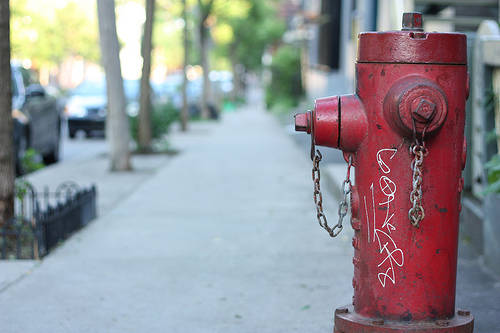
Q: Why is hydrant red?
A: Security.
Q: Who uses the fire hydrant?
A: Firemen.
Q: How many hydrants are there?
A: One.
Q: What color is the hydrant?
A: Red.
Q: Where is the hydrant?
A: On the sidewalk.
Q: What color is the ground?
A: Grey.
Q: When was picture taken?
A: Daytime.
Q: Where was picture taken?
A: On the sidewalk.